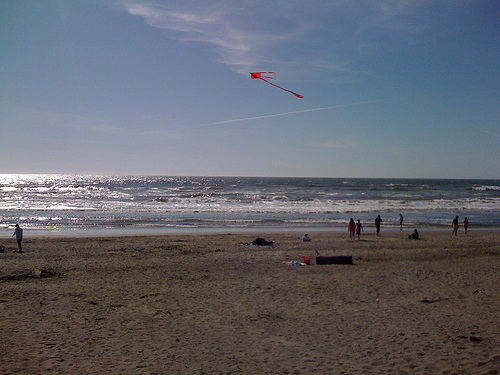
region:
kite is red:
[248, 71, 305, 100]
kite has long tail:
[250, 68, 303, 103]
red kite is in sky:
[247, 67, 302, 102]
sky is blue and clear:
[0, 0, 497, 179]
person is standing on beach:
[8, 220, 26, 252]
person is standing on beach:
[344, 217, 355, 239]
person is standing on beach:
[356, 216, 363, 240]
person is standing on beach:
[372, 212, 383, 236]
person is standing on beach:
[398, 212, 404, 228]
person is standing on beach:
[448, 213, 458, 233]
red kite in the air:
[242, 63, 312, 104]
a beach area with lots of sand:
[11, 240, 468, 368]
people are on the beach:
[338, 210, 365, 238]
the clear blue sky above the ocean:
[31, 23, 359, 148]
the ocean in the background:
[1, 169, 498, 231]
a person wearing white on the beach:
[13, 223, 27, 248]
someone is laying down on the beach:
[281, 253, 306, 273]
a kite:
[241, 67, 318, 107]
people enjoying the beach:
[341, 192, 481, 252]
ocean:
[12, 171, 490, 228]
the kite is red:
[246, 63, 309, 103]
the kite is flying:
[241, 65, 308, 102]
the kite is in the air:
[243, 58, 307, 105]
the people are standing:
[343, 210, 474, 240]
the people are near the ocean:
[346, 211, 472, 241]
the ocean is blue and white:
[35, 177, 498, 212]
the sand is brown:
[23, 287, 498, 372]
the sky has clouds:
[156, 7, 311, 51]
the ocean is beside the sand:
[58, 180, 247, 335]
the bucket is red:
[303, 253, 312, 269]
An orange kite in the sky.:
[248, 67, 304, 99]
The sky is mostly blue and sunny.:
[0, 0, 495, 176]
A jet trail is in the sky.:
[213, 98, 383, 127]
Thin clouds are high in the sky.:
[118, 0, 408, 84]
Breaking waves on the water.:
[0, 175, 498, 225]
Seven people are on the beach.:
[347, 212, 470, 238]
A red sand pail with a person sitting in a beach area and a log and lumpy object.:
[251, 230, 356, 268]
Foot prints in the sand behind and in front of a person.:
[1, 224, 217, 256]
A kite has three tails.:
[250, 70, 308, 99]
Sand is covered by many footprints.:
[0, 225, 499, 373]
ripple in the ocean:
[63, 183, 79, 194]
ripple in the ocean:
[117, 191, 137, 203]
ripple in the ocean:
[232, 200, 248, 206]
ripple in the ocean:
[307, 205, 327, 213]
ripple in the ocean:
[121, 197, 134, 210]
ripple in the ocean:
[52, 197, 67, 217]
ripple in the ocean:
[133, 170, 144, 180]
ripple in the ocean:
[21, 197, 36, 212]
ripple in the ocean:
[468, 197, 479, 207]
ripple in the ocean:
[368, 186, 384, 203]